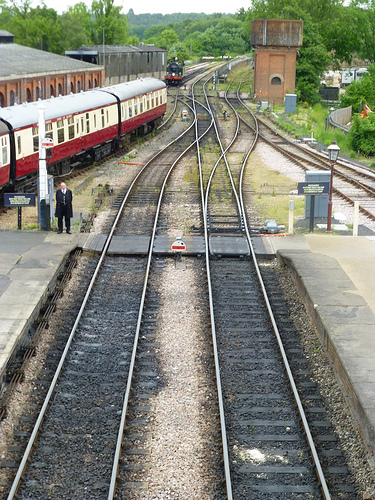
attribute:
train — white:
[0, 77, 166, 210]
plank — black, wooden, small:
[233, 484, 357, 493]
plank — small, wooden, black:
[4, 441, 152, 456]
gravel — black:
[0, 65, 369, 498]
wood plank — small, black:
[219, 325, 269, 331]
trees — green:
[0, 0, 255, 62]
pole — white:
[28, 101, 64, 229]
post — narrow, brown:
[322, 143, 339, 230]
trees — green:
[7, 1, 374, 101]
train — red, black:
[161, 35, 215, 105]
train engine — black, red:
[163, 53, 195, 95]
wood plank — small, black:
[205, 385, 323, 402]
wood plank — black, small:
[209, 370, 320, 397]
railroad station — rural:
[2, 6, 374, 498]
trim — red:
[11, 155, 55, 171]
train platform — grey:
[5, 233, 52, 326]